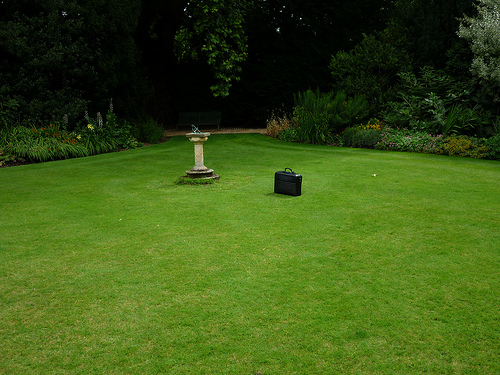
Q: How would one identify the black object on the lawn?
A: Suitcase.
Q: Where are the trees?
A: At the back of the scene.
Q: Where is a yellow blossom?
A: Left rear of the scene.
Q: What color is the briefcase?
A: Black.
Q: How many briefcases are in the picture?
A: One.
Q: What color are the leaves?
A: Dark green.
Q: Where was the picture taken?
A: A garden.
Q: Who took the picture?
A: The homeowner.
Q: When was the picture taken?
A: In the morning.